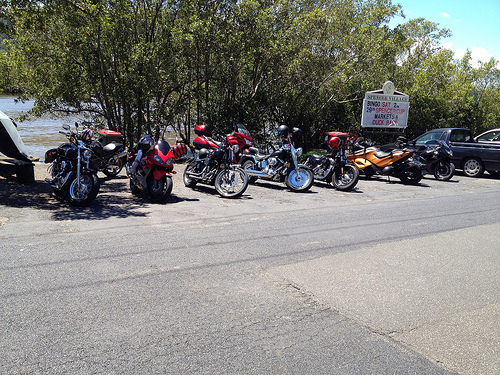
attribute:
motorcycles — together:
[36, 107, 462, 210]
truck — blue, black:
[420, 119, 500, 176]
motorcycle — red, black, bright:
[177, 113, 256, 203]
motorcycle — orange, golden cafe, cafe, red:
[350, 135, 430, 187]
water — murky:
[4, 87, 103, 153]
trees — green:
[6, 1, 492, 128]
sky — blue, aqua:
[405, 4, 494, 34]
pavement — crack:
[257, 259, 448, 375]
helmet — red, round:
[325, 132, 346, 155]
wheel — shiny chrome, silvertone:
[287, 163, 316, 192]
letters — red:
[373, 105, 406, 112]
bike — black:
[27, 120, 108, 212]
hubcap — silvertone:
[69, 173, 92, 201]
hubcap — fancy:
[289, 168, 309, 190]